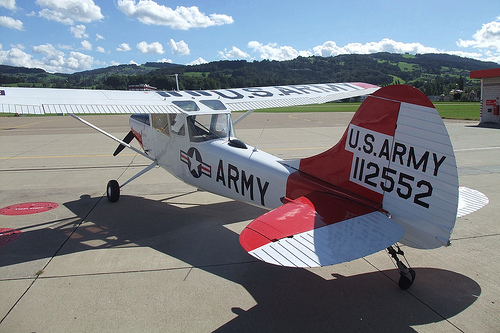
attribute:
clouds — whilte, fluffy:
[38, 2, 105, 29]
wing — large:
[0, 82, 381, 122]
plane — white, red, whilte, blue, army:
[2, 80, 491, 298]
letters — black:
[214, 156, 270, 210]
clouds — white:
[34, 0, 235, 38]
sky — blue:
[3, 2, 497, 72]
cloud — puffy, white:
[38, 0, 236, 34]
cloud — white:
[0, 15, 27, 31]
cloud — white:
[2, 1, 18, 11]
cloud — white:
[36, 9, 76, 25]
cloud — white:
[114, 0, 235, 33]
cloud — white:
[113, 42, 131, 53]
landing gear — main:
[102, 154, 157, 199]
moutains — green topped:
[222, 55, 442, 84]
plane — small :
[69, 67, 453, 307]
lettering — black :
[334, 110, 443, 210]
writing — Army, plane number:
[345, 122, 444, 220]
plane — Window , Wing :
[14, 55, 483, 328]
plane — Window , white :
[7, 59, 484, 306]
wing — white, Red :
[8, 59, 375, 169]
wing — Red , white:
[239, 169, 403, 289]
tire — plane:
[101, 176, 127, 202]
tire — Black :
[390, 261, 418, 282]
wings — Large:
[0, 80, 387, 113]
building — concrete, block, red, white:
[470, 66, 499, 121]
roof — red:
[468, 63, 498, 76]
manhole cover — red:
[2, 199, 57, 214]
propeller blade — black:
[114, 130, 134, 155]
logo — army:
[179, 146, 211, 178]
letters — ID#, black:
[350, 129, 447, 207]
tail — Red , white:
[284, 82, 454, 249]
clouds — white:
[1, 1, 499, 74]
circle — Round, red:
[1, 200, 59, 215]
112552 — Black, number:
[352, 157, 432, 209]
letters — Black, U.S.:
[348, 124, 377, 155]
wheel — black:
[397, 266, 417, 289]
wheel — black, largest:
[106, 180, 120, 204]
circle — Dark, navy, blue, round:
[184, 144, 203, 178]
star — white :
[185, 151, 199, 171]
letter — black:
[348, 129, 360, 147]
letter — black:
[361, 133, 375, 152]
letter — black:
[379, 137, 391, 159]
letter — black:
[392, 142, 408, 163]